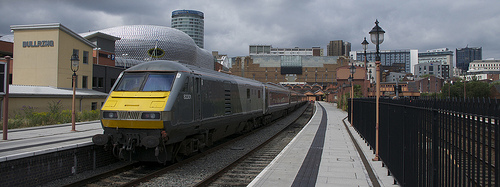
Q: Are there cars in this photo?
A: No, there are no cars.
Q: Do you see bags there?
A: No, there are no bags.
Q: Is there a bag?
A: No, there are no bags.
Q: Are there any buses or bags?
A: No, there are no bags or buses.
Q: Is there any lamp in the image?
A: Yes, there is a lamp.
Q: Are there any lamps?
A: Yes, there is a lamp.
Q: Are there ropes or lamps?
A: Yes, there is a lamp.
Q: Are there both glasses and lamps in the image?
A: No, there is a lamp but no glasses.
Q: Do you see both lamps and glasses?
A: No, there is a lamp but no glasses.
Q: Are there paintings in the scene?
A: No, there are no paintings.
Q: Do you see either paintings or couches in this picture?
A: No, there are no paintings or couches.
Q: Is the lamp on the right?
A: Yes, the lamp is on the right of the image.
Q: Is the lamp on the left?
A: No, the lamp is on the right of the image.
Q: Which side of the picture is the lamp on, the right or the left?
A: The lamp is on the right of the image.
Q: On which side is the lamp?
A: The lamp is on the right of the image.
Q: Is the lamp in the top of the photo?
A: Yes, the lamp is in the top of the image.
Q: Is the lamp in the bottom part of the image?
A: No, the lamp is in the top of the image.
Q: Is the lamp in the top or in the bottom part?
A: The lamp is in the top of the image.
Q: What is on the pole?
A: The lamp is on the pole.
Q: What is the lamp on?
A: The lamp is on the pole.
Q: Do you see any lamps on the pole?
A: Yes, there is a lamp on the pole.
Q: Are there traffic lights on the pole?
A: No, there is a lamp on the pole.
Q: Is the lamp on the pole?
A: Yes, the lamp is on the pole.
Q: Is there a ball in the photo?
A: No, there are no balls.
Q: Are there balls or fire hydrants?
A: No, there are no balls or fire hydrants.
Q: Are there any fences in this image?
A: Yes, there is a fence.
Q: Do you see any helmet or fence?
A: Yes, there is a fence.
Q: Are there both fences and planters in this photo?
A: No, there is a fence but no planters.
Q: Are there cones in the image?
A: No, there are no cones.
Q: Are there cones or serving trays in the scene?
A: No, there are no cones or serving trays.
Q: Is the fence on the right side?
A: Yes, the fence is on the right of the image.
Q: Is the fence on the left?
A: No, the fence is on the right of the image.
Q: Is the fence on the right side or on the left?
A: The fence is on the right of the image.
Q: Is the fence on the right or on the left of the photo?
A: The fence is on the right of the image.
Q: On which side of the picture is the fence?
A: The fence is on the right of the image.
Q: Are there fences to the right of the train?
A: Yes, there is a fence to the right of the train.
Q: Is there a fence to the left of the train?
A: No, the fence is to the right of the train.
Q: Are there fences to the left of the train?
A: No, the fence is to the right of the train.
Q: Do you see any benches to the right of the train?
A: No, there is a fence to the right of the train.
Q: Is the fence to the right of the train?
A: Yes, the fence is to the right of the train.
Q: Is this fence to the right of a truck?
A: No, the fence is to the right of the train.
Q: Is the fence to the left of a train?
A: No, the fence is to the right of a train.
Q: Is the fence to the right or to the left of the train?
A: The fence is to the right of the train.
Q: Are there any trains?
A: Yes, there is a train.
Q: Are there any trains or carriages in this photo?
A: Yes, there is a train.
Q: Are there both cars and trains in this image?
A: No, there is a train but no cars.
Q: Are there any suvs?
A: No, there are no suvs.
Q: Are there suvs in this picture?
A: No, there are no suvs.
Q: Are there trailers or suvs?
A: No, there are no suvs or trailers.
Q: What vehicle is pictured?
A: The vehicle is a train.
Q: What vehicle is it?
A: The vehicle is a train.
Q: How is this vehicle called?
A: That is a train.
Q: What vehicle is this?
A: That is a train.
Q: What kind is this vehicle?
A: That is a train.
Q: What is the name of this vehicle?
A: That is a train.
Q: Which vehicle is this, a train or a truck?
A: That is a train.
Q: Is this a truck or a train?
A: This is a train.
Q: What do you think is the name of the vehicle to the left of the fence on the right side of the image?
A: The vehicle is a train.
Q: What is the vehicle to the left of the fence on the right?
A: The vehicle is a train.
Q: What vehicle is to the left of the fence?
A: The vehicle is a train.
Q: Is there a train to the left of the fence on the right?
A: Yes, there is a train to the left of the fence.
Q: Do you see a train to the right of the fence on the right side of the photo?
A: No, the train is to the left of the fence.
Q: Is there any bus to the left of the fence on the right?
A: No, there is a train to the left of the fence.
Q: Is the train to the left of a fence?
A: Yes, the train is to the left of a fence.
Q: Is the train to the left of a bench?
A: No, the train is to the left of a fence.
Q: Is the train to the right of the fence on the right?
A: No, the train is to the left of the fence.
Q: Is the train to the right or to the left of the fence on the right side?
A: The train is to the left of the fence.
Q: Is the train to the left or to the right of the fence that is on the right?
A: The train is to the left of the fence.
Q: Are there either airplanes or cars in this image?
A: No, there are no cars or airplanes.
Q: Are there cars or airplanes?
A: No, there are no cars or airplanes.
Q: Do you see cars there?
A: No, there are no cars.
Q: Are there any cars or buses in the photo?
A: No, there are no cars or buses.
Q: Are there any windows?
A: Yes, there is a window.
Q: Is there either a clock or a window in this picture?
A: Yes, there is a window.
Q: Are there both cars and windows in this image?
A: No, there is a window but no cars.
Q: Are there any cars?
A: No, there are no cars.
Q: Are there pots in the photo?
A: No, there are no pots.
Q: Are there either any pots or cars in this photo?
A: No, there are no pots or cars.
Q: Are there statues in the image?
A: No, there are no statues.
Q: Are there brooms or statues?
A: No, there are no statues or brooms.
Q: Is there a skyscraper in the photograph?
A: Yes, there is a skyscraper.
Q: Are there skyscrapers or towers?
A: Yes, there is a skyscraper.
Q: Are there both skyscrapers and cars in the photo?
A: No, there is a skyscraper but no cars.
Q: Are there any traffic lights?
A: No, there are no traffic lights.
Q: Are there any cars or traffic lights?
A: No, there are no traffic lights or cars.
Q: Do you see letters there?
A: Yes, there are letters.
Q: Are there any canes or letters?
A: Yes, there are letters.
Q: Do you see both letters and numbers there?
A: No, there are letters but no numbers.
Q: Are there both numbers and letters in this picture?
A: No, there are letters but no numbers.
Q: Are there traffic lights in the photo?
A: No, there are no traffic lights.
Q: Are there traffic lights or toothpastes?
A: No, there are no traffic lights or toothpastes.